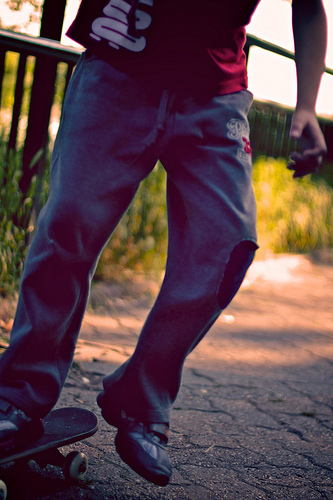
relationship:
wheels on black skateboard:
[61, 449, 90, 479] [0, 400, 99, 495]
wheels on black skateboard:
[1, 473, 11, 499] [0, 400, 99, 495]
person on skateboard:
[0, 0, 326, 475] [0, 404, 99, 497]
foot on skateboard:
[0, 392, 42, 454] [0, 404, 99, 497]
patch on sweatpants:
[215, 237, 258, 310] [0, 45, 274, 427]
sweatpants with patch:
[0, 45, 274, 427] [215, 237, 258, 310]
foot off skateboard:
[84, 377, 183, 485] [0, 404, 99, 497]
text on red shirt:
[89, 1, 156, 53] [63, 0, 261, 93]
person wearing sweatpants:
[0, 0, 326, 488] [0, 45, 274, 427]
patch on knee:
[215, 237, 258, 310] [219, 241, 262, 272]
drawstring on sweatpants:
[143, 85, 180, 145] [0, 45, 260, 427]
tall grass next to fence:
[1, 129, 331, 269] [2, 0, 332, 215]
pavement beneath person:
[205, 385, 324, 453] [0, 0, 326, 488]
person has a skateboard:
[0, 0, 326, 488] [4, 401, 101, 495]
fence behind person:
[0, 30, 332, 251] [0, 0, 326, 488]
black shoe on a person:
[97, 385, 175, 483] [23, 3, 316, 469]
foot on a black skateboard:
[0, 392, 42, 454] [0, 406, 99, 499]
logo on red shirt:
[87, 0, 157, 51] [63, 0, 261, 93]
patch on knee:
[215, 237, 258, 310] [213, 223, 263, 282]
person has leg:
[0, 0, 326, 488] [166, 151, 273, 341]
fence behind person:
[0, 26, 326, 251] [0, 0, 326, 488]